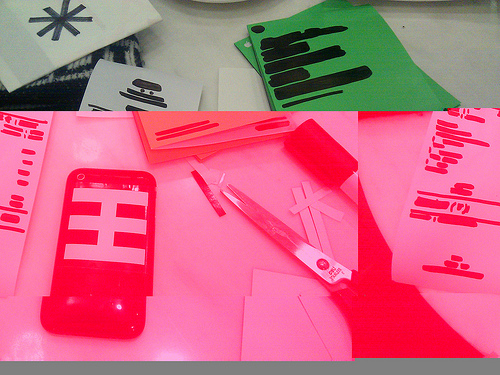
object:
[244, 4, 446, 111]
cards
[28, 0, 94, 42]
star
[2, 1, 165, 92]
card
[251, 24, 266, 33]
dot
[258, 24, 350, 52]
lines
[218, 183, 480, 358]
scissors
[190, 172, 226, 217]
thin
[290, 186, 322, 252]
strips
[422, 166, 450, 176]
items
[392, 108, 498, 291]
receipt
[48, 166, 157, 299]
cell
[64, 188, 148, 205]
lines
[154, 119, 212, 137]
lines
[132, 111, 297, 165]
bottom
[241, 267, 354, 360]
paper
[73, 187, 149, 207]
white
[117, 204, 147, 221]
black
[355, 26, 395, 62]
green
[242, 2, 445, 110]
top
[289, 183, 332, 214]
paper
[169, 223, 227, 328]
pink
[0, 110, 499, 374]
table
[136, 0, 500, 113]
table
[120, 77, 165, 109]
black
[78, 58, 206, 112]
paper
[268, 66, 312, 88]
black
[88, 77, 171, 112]
marker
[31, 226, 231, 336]
red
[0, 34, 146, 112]
hat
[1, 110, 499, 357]
picture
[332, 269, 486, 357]
bottom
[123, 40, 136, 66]
grey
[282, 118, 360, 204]
something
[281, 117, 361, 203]
bottle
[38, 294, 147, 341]
case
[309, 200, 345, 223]
things